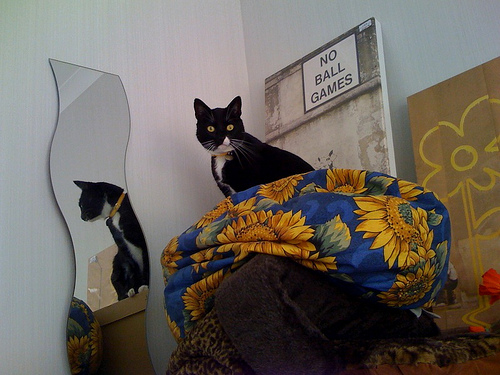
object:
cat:
[193, 96, 316, 198]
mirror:
[48, 58, 152, 374]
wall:
[1, 1, 257, 372]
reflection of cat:
[72, 180, 150, 301]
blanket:
[161, 169, 450, 344]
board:
[263, 17, 397, 177]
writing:
[311, 50, 352, 103]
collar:
[213, 151, 234, 161]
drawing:
[314, 150, 338, 170]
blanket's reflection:
[67, 296, 102, 375]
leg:
[220, 188, 237, 198]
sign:
[301, 32, 361, 115]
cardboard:
[406, 58, 500, 334]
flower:
[419, 94, 500, 328]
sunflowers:
[161, 167, 449, 347]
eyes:
[207, 124, 234, 132]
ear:
[226, 96, 242, 119]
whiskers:
[228, 138, 256, 160]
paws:
[128, 284, 148, 297]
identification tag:
[225, 154, 234, 161]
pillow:
[215, 252, 438, 373]